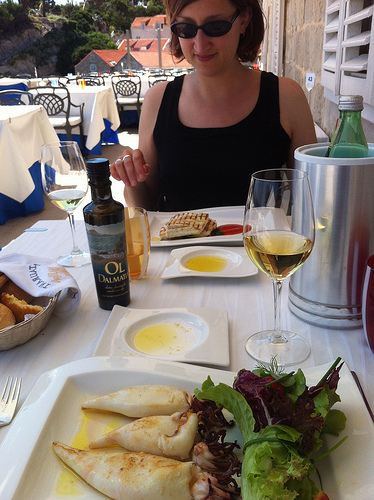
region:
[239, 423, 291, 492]
this is a broccoli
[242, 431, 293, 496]
the broccoli is green in color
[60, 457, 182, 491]
this is fried lobster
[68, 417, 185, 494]
the lobsters are cream in collor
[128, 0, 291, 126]
this is a lady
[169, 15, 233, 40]
she is wearing goggles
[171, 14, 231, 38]
the goggles are black in color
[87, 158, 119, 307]
this is a bottle of wine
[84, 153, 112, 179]
the top[ is closed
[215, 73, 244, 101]
the lady is light skinned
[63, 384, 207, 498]
poached chicken on plate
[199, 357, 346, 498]
mixed greens on plate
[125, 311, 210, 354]
oil in white bowl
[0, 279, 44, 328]
bread slices in bowl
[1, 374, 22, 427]
silver metal dinner fork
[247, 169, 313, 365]
wine glass on table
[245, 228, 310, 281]
white wine in glass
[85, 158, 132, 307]
olive oil bottle on table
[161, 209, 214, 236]
grilled cheese on plate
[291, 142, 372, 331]
silver metal wine bucket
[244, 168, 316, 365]
wine class on table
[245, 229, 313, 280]
white wine in wine glass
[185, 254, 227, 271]
olive oil in shallow white bowl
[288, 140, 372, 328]
silver metal ice bucket on table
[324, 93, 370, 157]
green glass bottle inside ice bucket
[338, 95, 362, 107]
silver metal screw top on bottle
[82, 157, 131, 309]
dark glass bottle on table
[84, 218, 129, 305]
label on bottle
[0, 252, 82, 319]
white cloth napkin on basket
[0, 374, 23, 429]
fork next to white plate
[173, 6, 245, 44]
black plastic sunglasses on woman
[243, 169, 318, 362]
clear wine glass on white table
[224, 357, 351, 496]
garden salad on white plate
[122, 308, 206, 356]
garlic butter sauce on white saucer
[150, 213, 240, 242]
grilled fish with red sauce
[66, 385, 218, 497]
baked squid on white plate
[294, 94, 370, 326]
wine bottle in metal ice bucket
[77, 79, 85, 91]
candle on white table in background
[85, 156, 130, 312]
ol dalmation sauce bottle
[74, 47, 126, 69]
red roof on top of brick house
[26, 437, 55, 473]
edge of a dish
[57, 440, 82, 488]
edge of a food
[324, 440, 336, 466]
edge of a tray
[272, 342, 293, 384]
part of a glass